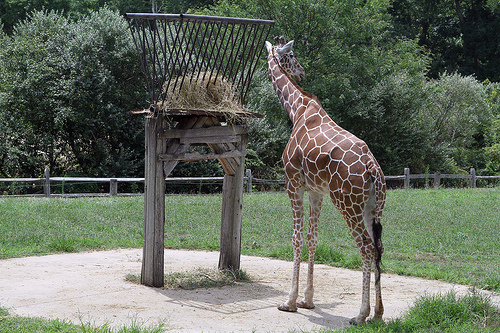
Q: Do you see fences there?
A: Yes, there is a fence.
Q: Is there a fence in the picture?
A: Yes, there is a fence.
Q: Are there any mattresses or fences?
A: Yes, there is a fence.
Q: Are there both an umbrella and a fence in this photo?
A: No, there is a fence but no umbrellas.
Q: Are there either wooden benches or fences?
A: Yes, there is a wood fence.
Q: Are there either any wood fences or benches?
A: Yes, there is a wood fence.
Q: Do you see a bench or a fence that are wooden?
A: Yes, the fence is wooden.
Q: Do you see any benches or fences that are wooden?
A: Yes, the fence is wooden.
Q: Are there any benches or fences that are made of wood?
A: Yes, the fence is made of wood.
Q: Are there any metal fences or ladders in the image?
A: Yes, there is a metal fence.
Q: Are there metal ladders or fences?
A: Yes, there is a metal fence.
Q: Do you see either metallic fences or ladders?
A: Yes, there is a metal fence.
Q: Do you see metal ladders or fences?
A: Yes, there is a metal fence.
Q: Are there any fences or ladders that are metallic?
A: Yes, the fence is metallic.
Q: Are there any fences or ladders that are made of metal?
A: Yes, the fence is made of metal.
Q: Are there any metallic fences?
A: Yes, there is a metal fence.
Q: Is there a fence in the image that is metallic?
A: Yes, there is a fence that is metallic.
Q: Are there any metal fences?
A: Yes, there is a fence that is made of metal.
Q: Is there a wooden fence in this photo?
A: Yes, there is a wood fence.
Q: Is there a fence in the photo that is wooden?
A: Yes, there is a fence that is wooden.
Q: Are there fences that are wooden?
A: Yes, there is a fence that is wooden.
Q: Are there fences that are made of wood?
A: Yes, there is a fence that is made of wood.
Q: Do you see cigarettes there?
A: No, there are no cigarettes.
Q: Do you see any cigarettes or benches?
A: No, there are no cigarettes or benches.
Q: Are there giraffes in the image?
A: Yes, there is a giraffe.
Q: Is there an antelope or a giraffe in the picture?
A: Yes, there is a giraffe.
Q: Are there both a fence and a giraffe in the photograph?
A: Yes, there are both a giraffe and a fence.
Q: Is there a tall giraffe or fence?
A: Yes, there is a tall giraffe.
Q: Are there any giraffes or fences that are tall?
A: Yes, the giraffe is tall.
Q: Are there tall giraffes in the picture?
A: Yes, there is a tall giraffe.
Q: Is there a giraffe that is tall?
A: Yes, there is a giraffe that is tall.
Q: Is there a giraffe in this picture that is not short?
A: Yes, there is a tall giraffe.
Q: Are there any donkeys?
A: No, there are no donkeys.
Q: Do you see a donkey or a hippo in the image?
A: No, there are no donkeys or hippoes.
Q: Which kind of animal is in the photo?
A: The animal is a giraffe.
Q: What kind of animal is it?
A: The animal is a giraffe.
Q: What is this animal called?
A: This is a giraffe.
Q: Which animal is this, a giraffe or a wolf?
A: This is a giraffe.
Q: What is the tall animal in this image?
A: The animal is a giraffe.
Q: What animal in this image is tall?
A: The animal is a giraffe.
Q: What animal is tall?
A: The animal is a giraffe.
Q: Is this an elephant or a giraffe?
A: This is a giraffe.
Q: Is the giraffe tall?
A: Yes, the giraffe is tall.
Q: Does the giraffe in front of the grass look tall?
A: Yes, the giraffe is tall.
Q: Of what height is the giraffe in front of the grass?
A: The giraffe is tall.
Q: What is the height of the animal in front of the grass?
A: The giraffe is tall.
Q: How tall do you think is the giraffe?
A: The giraffe is tall.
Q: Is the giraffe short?
A: No, the giraffe is tall.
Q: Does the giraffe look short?
A: No, the giraffe is tall.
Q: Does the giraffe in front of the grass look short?
A: No, the giraffe is tall.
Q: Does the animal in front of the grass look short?
A: No, the giraffe is tall.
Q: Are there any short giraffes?
A: No, there is a giraffe but it is tall.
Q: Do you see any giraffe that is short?
A: No, there is a giraffe but it is tall.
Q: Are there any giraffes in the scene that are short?
A: No, there is a giraffe but it is tall.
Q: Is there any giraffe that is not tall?
A: No, there is a giraffe but it is tall.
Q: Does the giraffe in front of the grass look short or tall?
A: The giraffe is tall.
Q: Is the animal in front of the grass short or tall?
A: The giraffe is tall.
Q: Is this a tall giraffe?
A: Yes, this is a tall giraffe.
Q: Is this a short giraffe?
A: No, this is a tall giraffe.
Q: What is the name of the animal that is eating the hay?
A: The animal is a giraffe.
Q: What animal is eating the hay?
A: The animal is a giraffe.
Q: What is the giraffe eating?
A: The giraffe is eating hay.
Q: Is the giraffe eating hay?
A: Yes, the giraffe is eating hay.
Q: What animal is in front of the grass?
A: The giraffe is in front of the grass.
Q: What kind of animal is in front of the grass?
A: The animal is a giraffe.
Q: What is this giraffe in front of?
A: The giraffe is in front of the grass.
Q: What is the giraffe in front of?
A: The giraffe is in front of the grass.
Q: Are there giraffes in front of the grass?
A: Yes, there is a giraffe in front of the grass.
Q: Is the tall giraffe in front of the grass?
A: Yes, the giraffe is in front of the grass.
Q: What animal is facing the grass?
A: The giraffe is facing the grass.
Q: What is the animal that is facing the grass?
A: The animal is a giraffe.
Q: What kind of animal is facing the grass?
A: The animal is a giraffe.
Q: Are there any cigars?
A: No, there are no cigars.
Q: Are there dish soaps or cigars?
A: No, there are no cigars or dish soaps.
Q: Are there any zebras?
A: No, there are no zebras.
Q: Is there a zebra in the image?
A: No, there are no zebras.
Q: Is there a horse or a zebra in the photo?
A: No, there are no zebras or horses.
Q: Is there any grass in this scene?
A: Yes, there is grass.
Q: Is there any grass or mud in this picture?
A: Yes, there is grass.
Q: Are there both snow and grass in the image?
A: No, there is grass but no snow.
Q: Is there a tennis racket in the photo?
A: No, there are no rackets.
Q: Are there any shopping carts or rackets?
A: No, there are no rackets or shopping carts.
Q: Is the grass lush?
A: Yes, the grass is lush.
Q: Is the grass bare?
A: No, the grass is lush.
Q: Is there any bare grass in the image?
A: No, there is grass but it is lush.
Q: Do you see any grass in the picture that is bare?
A: No, there is grass but it is lush.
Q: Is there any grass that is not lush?
A: No, there is grass but it is lush.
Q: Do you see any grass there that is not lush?
A: No, there is grass but it is lush.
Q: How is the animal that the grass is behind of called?
A: The animal is a giraffe.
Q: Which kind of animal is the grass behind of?
A: The grass is behind the giraffe.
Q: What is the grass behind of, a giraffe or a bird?
A: The grass is behind a giraffe.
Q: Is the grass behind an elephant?
A: No, the grass is behind a giraffe.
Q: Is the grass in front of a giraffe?
A: No, the grass is behind a giraffe.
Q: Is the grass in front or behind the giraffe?
A: The grass is behind the giraffe.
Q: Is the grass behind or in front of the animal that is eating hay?
A: The grass is behind the giraffe.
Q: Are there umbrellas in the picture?
A: No, there are no umbrellas.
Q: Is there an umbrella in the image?
A: No, there are no umbrellas.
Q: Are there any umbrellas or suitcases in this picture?
A: No, there are no umbrellas or suitcases.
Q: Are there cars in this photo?
A: No, there are no cars.